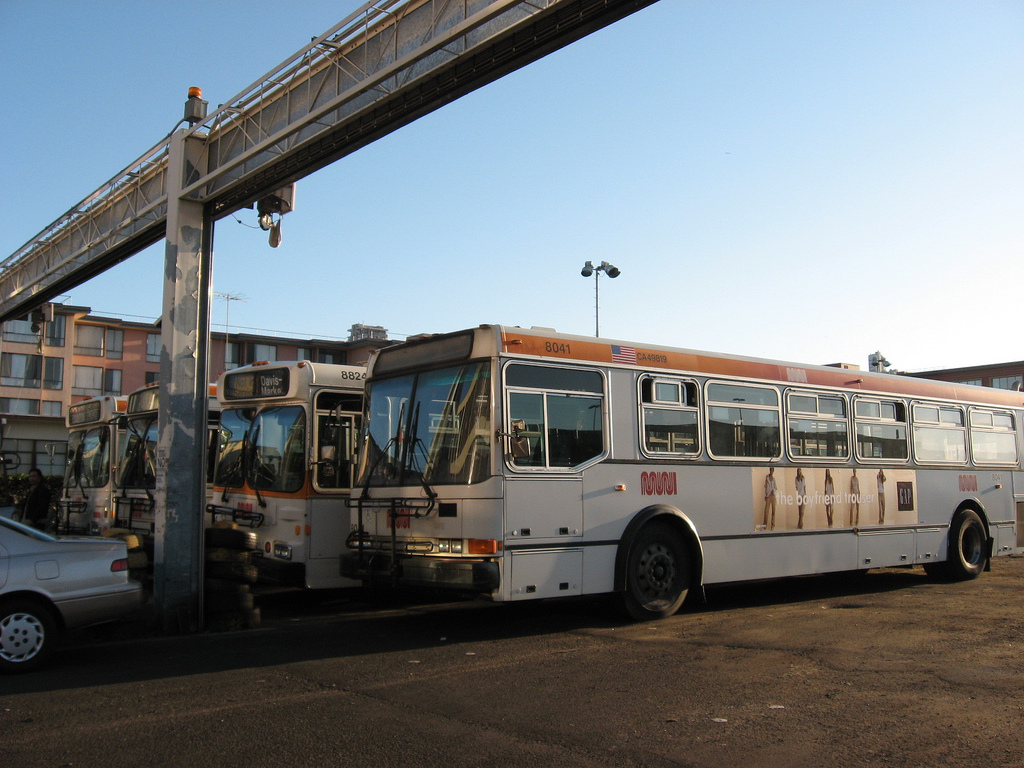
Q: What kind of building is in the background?
A: An apartment building.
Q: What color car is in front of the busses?
A: Silver.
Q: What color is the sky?
A: Blue.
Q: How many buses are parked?
A: 4.